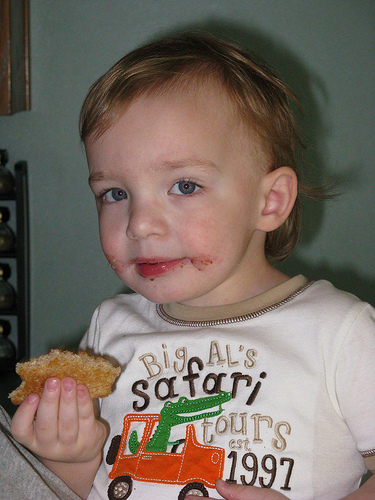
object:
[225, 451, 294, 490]
date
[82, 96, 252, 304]
face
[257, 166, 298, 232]
ear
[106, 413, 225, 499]
truck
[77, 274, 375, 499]
shirt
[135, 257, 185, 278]
mouth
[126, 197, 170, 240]
nose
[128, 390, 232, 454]
alligator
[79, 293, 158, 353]
shoulder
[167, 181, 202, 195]
eye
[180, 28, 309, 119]
cowlick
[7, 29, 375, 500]
child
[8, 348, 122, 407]
bread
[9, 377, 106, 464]
boy's hand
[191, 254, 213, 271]
food